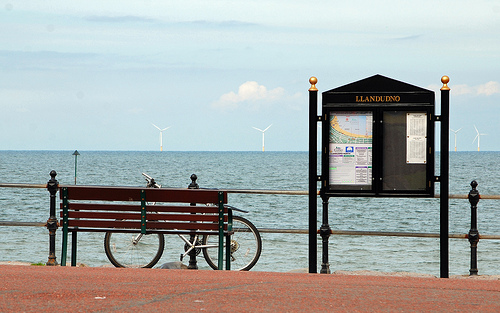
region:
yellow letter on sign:
[351, 93, 361, 102]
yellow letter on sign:
[358, 93, 363, 105]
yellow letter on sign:
[362, 93, 370, 103]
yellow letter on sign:
[367, 93, 375, 103]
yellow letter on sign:
[373, 94, 380, 101]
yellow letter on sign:
[377, 94, 387, 103]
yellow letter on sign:
[383, 93, 390, 101]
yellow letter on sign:
[388, 93, 393, 102]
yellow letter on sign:
[393, 94, 400, 104]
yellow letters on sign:
[353, 90, 405, 105]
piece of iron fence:
[1, 180, 46, 192]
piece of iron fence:
[0, 215, 50, 228]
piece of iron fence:
[42, 168, 63, 264]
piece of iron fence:
[222, 185, 314, 198]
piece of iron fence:
[231, 220, 307, 235]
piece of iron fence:
[311, 180, 340, 271]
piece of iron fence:
[329, 225, 443, 242]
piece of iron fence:
[462, 179, 482, 274]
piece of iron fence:
[433, 71, 457, 281]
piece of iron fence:
[1, 179, 54, 193]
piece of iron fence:
[1, 215, 46, 232]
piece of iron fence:
[52, 182, 307, 199]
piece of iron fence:
[331, 187, 471, 204]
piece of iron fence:
[330, 223, 468, 246]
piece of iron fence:
[461, 177, 486, 275]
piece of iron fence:
[478, 190, 498, 202]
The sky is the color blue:
[8, 22, 296, 97]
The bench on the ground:
[48, 175, 238, 272]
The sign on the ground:
[296, 58, 468, 282]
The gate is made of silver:
[231, 180, 498, 260]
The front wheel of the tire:
[101, 208, 165, 271]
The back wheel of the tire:
[201, 211, 263, 273]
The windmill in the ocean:
[141, 117, 276, 157]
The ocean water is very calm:
[20, 141, 303, 192]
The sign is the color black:
[287, 65, 461, 277]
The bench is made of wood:
[55, 181, 237, 242]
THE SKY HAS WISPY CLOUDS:
[2, 0, 495, 152]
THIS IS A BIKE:
[90, 158, 270, 288]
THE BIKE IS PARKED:
[100, 165, 268, 276]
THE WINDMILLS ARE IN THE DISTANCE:
[130, 110, 495, 151]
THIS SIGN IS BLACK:
[300, 63, 456, 280]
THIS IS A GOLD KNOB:
[305, 67, 320, 93]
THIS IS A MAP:
[331, 103, 371, 189]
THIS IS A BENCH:
[53, 180, 235, 271]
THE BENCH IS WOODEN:
[55, 181, 238, 273]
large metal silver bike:
[104, 173, 262, 268]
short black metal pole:
[465, 179, 482, 279]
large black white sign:
[320, 74, 435, 198]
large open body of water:
[0, 149, 499, 276]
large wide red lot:
[1, 262, 498, 310]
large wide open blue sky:
[1, 3, 498, 148]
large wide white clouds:
[209, 80, 309, 108]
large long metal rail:
[0, 181, 499, 242]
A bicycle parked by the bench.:
[118, 168, 275, 278]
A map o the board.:
[328, 115, 375, 143]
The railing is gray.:
[238, 178, 498, 245]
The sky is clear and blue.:
[52, 35, 485, 132]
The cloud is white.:
[206, 70, 314, 115]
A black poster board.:
[306, 61, 446, 194]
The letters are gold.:
[352, 88, 410, 108]